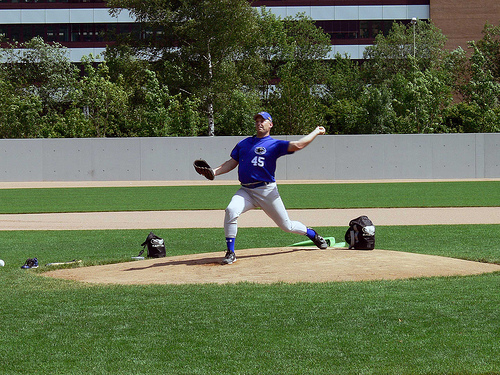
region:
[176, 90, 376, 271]
baseball player on mound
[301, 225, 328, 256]
black shoe of player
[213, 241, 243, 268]
black shoe of player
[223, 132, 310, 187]
blue jersey on player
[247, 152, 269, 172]
number 45 on player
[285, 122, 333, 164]
pitching arm of player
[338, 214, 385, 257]
black book bag on dirt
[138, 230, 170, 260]
black book bag on grass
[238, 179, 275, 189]
belt around player's pants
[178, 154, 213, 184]
baseball mitt on hand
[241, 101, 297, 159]
Person wearing blue baseball hat.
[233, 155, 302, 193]
Person wearing blue shirt.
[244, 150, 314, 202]
Number 45 on person's shirt.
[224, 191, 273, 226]
Person wearing white pants.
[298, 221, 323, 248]
Person wearing blue socks.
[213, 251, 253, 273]
Person wearing black shoes.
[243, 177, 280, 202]
Person wearing blue belt.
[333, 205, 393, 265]
Black bag sitting on ground.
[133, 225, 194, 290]
Black bag sitting on ground.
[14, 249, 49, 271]
Tennis shoe sitting in grass.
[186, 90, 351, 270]
baseball player on pitching mound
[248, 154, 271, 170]
number on front of jersey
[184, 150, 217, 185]
glove on right hand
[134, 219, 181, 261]
bag on grass beside base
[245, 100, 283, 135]
blue hat on head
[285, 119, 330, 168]
left arm of pitcher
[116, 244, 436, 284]
dirt pitching mound for pitcher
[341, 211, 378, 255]
black book bag for pitcher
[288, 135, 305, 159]
elbow of pitcher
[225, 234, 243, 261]
blue sock on player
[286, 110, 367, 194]
Man throwing a ball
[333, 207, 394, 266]
Black bag on a pitchers mound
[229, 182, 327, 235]
Man wearing white pants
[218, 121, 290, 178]
Man wearing blue jersey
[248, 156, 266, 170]
Number 45 on Jersey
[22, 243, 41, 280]
Sneakers in the grass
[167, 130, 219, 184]
Man wearing baseball glove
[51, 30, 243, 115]
Trees behind baseball field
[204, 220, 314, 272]
Pitchers mound surround by grass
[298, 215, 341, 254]
Green plate on mound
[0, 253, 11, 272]
white ball on grass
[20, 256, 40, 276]
pair of blue base ball cleats on grass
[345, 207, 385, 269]
black backpack on mount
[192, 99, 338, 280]
pitcher sanding on mound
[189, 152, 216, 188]
pitcher's glove is brown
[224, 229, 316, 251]
man is wearing blue socks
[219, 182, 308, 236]
man pants is white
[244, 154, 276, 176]
number 45 on baseball jersey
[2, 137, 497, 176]
tall white wall in background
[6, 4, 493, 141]
trees behind white wall